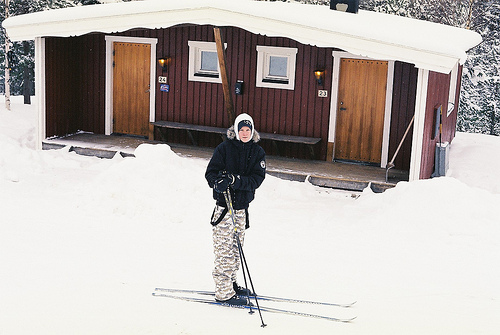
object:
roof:
[1, 4, 488, 74]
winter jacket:
[210, 139, 265, 207]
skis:
[152, 281, 357, 322]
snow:
[0, 156, 499, 329]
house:
[5, 2, 467, 181]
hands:
[219, 173, 237, 187]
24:
[157, 72, 168, 85]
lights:
[156, 55, 325, 86]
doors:
[103, 37, 390, 167]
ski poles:
[242, 256, 270, 328]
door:
[336, 55, 387, 167]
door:
[108, 36, 153, 138]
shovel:
[362, 115, 420, 176]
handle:
[386, 111, 430, 150]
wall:
[377, 67, 421, 122]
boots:
[224, 282, 248, 308]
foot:
[227, 295, 250, 306]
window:
[257, 47, 301, 91]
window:
[187, 38, 229, 85]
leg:
[212, 207, 239, 299]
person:
[209, 112, 258, 309]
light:
[309, 70, 323, 81]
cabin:
[4, 2, 482, 194]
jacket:
[207, 146, 267, 205]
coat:
[190, 129, 281, 220]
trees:
[0, 2, 498, 133]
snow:
[6, 0, 465, 35]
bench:
[156, 118, 320, 158]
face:
[236, 124, 253, 144]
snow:
[202, 0, 480, 51]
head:
[233, 109, 255, 143]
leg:
[233, 205, 246, 288]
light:
[156, 51, 169, 70]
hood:
[225, 109, 264, 146]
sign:
[156, 74, 166, 84]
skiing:
[150, 175, 356, 326]